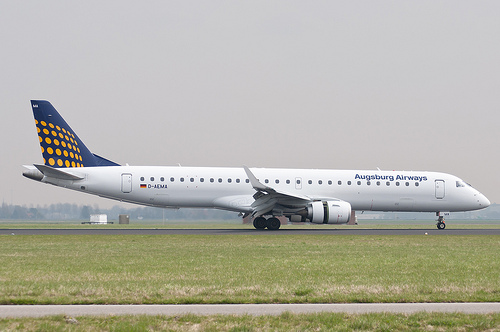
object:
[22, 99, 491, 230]
plane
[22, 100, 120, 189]
tail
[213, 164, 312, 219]
wing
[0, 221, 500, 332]
grass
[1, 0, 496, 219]
sky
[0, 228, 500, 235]
runway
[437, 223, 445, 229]
wheel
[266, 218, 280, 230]
wheel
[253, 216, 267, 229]
wheel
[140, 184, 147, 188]
flag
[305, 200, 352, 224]
engine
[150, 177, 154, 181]
window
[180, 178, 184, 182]
window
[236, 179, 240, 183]
window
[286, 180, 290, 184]
window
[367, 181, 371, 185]
window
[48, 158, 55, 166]
dot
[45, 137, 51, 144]
dot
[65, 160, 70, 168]
dot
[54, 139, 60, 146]
dot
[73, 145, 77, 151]
dot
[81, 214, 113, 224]
structure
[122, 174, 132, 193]
backdoor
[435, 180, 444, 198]
front door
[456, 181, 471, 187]
cockpit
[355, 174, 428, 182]
augsburg airways